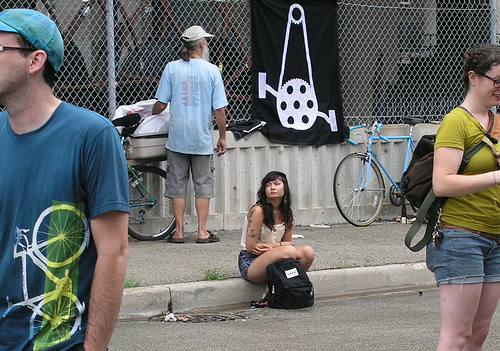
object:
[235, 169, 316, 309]
woman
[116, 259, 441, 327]
curb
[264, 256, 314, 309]
backpack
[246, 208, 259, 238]
tattoos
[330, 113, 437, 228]
bicycle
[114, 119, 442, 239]
wall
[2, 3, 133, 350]
man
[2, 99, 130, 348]
shirt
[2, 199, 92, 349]
design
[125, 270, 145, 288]
weeds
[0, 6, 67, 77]
hat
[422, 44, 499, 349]
woman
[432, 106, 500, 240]
shirt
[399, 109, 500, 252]
backpack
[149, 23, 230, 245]
old man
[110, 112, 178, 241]
bicycle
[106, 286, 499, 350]
street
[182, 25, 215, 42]
hat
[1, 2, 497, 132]
fence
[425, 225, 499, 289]
shorts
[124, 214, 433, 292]
sidewalk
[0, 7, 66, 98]
head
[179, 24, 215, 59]
head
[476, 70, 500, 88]
glasses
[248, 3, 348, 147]
banner